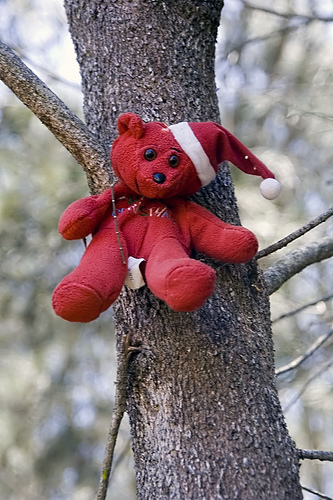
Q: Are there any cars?
A: No, there are no cars.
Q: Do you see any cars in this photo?
A: No, there are no cars.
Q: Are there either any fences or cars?
A: No, there are no cars or fences.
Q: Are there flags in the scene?
A: No, there are no flags.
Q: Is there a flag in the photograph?
A: No, there are no flags.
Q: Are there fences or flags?
A: No, there are no flags or fences.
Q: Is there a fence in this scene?
A: No, there are no fences.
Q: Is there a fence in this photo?
A: No, there are no fences.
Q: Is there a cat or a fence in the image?
A: No, there are no fences or cats.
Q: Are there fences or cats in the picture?
A: No, there are no fences or cats.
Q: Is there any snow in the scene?
A: Yes, there is snow.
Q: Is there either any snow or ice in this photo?
A: Yes, there is snow.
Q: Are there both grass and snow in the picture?
A: No, there is snow but no grass.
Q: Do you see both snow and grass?
A: No, there is snow but no grass.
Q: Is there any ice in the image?
A: No, there is no ice.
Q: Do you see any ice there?
A: No, there is no ice.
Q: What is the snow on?
A: The snow is on the branches.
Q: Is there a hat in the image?
A: Yes, there is a hat.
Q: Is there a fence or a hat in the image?
A: Yes, there is a hat.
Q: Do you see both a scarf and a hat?
A: No, there is a hat but no scarves.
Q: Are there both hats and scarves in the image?
A: No, there is a hat but no scarves.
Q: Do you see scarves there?
A: No, there are no scarves.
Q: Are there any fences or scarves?
A: No, there are no scarves or fences.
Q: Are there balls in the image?
A: Yes, there is a ball.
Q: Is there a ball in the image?
A: Yes, there is a ball.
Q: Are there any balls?
A: Yes, there is a ball.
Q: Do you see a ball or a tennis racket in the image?
A: Yes, there is a ball.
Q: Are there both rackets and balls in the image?
A: No, there is a ball but no rackets.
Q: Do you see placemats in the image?
A: No, there are no placemats.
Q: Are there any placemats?
A: No, there are no placemats.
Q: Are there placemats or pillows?
A: No, there are no placemats or pillows.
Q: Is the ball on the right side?
A: Yes, the ball is on the right of the image.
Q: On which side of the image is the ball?
A: The ball is on the right of the image.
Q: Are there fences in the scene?
A: No, there are no fences.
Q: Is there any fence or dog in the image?
A: No, there are no fences or dogs.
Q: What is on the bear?
A: The tag is on the bear.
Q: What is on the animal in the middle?
A: The tag is on the bear.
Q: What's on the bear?
A: The tag is on the bear.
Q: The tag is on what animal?
A: The tag is on the bear.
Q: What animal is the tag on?
A: The tag is on the bear.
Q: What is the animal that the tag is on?
A: The animal is a bear.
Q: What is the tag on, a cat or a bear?
A: The tag is on a bear.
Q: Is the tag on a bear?
A: Yes, the tag is on a bear.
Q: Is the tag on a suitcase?
A: No, the tag is on a bear.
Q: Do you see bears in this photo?
A: Yes, there is a bear.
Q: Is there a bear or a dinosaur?
A: Yes, there is a bear.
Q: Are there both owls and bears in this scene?
A: No, there is a bear but no owls.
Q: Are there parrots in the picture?
A: No, there are no parrots.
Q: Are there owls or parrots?
A: No, there are no parrots or owls.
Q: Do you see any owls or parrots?
A: No, there are no parrots or owls.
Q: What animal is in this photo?
A: The animal is a bear.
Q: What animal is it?
A: The animal is a bear.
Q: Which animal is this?
A: This is a bear.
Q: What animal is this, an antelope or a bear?
A: This is a bear.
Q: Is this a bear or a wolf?
A: This is a bear.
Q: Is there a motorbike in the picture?
A: No, there are no motorcycles.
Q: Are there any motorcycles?
A: No, there are no motorcycles.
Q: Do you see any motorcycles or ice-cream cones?
A: No, there are no motorcycles or ice-cream cones.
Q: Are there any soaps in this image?
A: No, there are no soaps.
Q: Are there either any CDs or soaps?
A: No, there are no soaps or cds.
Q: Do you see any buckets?
A: No, there are no buckets.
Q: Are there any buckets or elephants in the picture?
A: No, there are no buckets or elephants.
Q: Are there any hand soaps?
A: No, there are no hand soaps.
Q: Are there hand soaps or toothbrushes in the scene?
A: No, there are no hand soaps or toothbrushes.